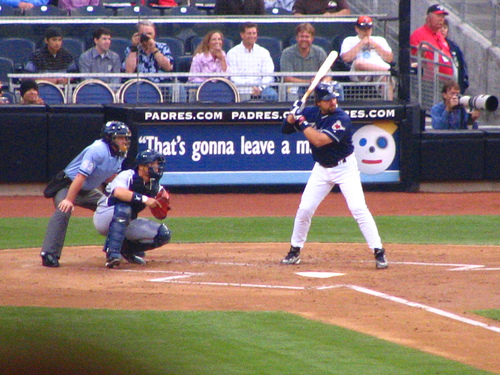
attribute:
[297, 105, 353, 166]
jersey — blue 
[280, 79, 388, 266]
player — up to bat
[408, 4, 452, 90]
man — older 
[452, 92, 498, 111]
telephoto lens — huge 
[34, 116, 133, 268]
umpire — crouching 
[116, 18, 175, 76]
man — taking photos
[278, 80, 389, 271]
man — playing 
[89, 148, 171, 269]
catcher — crouching , crouched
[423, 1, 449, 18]
shirt/cap — red/baseball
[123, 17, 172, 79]
man — taking a picture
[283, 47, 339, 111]
baseball bat — upraised, wooden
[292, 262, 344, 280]
home plate — white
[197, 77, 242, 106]
seat — blue, empty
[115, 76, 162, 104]
seat — blue, empty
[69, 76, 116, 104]
seat — blue, empty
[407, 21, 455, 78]
shirt — red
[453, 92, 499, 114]
lense — long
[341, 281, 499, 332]
line — white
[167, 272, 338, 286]
line — white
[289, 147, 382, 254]
pants — white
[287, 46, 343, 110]
bat — white 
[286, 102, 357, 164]
shirt — blue 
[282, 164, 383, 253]
pants — white 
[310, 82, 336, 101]
helmet — blue 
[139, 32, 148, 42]
camera — large 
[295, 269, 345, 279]
plate — white 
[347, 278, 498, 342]
line — white 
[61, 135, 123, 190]
shirt — blue 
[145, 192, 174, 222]
glove — leather , brown 